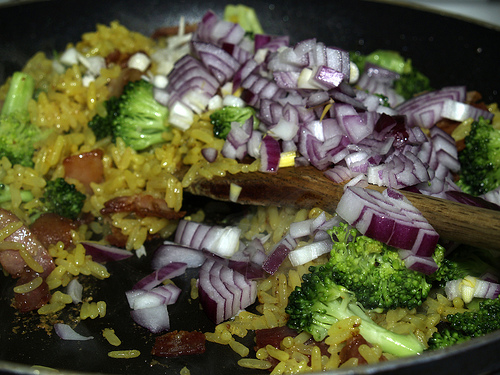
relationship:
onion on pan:
[344, 186, 445, 245] [7, 12, 494, 339]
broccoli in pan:
[284, 266, 423, 357] [7, 12, 494, 339]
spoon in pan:
[182, 163, 500, 265] [7, 12, 494, 339]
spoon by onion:
[182, 163, 500, 265] [157, 24, 461, 250]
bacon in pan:
[59, 148, 106, 184] [7, 12, 494, 339]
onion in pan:
[109, 207, 297, 334] [3, 7, 496, 367]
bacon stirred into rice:
[152, 328, 202, 363] [3, 22, 463, 373]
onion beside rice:
[194, 260, 269, 316] [53, 80, 85, 108]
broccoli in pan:
[73, 72, 202, 150] [7, 12, 494, 339]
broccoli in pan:
[325, 225, 432, 314] [7, 12, 494, 339]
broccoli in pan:
[425, 297, 497, 350] [7, 12, 494, 339]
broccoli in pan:
[460, 96, 498, 200] [7, 12, 494, 339]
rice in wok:
[79, 26, 154, 56] [7, 2, 499, 372]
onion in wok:
[435, 97, 492, 128] [368, 3, 490, 83]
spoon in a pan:
[187, 164, 497, 253] [3, 7, 496, 367]